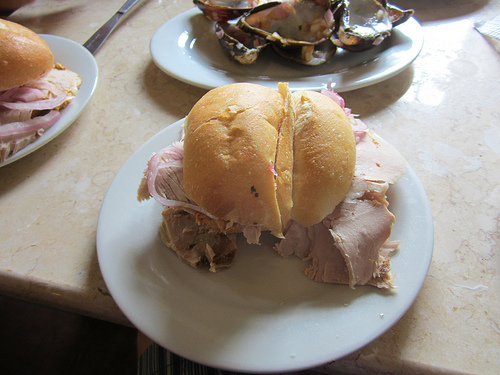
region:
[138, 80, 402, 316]
this is a sandwich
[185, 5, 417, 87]
this is a plate of food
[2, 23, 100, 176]
this is a plate of food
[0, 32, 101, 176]
this is a plate of food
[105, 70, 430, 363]
this is a plate of food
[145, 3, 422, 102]
this is a plate of food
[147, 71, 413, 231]
sandwich on the plate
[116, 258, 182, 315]
shadow on the plate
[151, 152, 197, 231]
meat in the sandwich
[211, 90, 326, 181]
brown bread on plate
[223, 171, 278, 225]
dark spot on bread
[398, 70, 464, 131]
light hitting the table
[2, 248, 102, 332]
edge of the table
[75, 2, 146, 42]
utensil next to the plate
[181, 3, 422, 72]
food on the plate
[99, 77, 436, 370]
this is a plate of food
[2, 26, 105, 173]
this is a plate of food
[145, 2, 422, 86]
this is a plate of food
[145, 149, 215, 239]
this is a ring of onion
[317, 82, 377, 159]
this is a ring of onion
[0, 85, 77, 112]
this is a ring of onion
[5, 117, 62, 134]
this is a ring of onion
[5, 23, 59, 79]
this is a piece of bread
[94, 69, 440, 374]
meat sandwich on white plate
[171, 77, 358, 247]
tan sandwich roll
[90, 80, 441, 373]
round white plate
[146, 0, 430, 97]
empty oyster shells on plate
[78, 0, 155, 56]
silver butter knife on table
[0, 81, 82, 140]
sliced onions on sandwich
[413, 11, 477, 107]
light reflecting on table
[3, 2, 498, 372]
cream colored marble table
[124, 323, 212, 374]
silver legs of table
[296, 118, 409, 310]
tan colored sandwich meat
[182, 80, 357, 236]
the top section of the bun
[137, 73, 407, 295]
the filled sandwich that hasn't been eaten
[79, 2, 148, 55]
the silver butter knife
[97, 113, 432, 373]
the round white plate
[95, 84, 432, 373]
the food on the white plate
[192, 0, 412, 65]
the empty clam shells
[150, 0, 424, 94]
the clam shells on the white plate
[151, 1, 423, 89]
the white plate under the clam shells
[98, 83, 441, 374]
sandwich on a plate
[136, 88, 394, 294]
meat on a sandwich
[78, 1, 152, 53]
knife on the table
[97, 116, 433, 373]
plate is white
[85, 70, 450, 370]
A sandwich on the plate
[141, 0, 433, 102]
A round white plate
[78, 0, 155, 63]
A silver butter knife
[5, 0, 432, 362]
white plates on the table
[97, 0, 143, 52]
silver knife on the table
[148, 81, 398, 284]
sandwich with pink meat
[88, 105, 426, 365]
plate hanging off the table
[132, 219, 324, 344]
shadow on the white plate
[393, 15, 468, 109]
light reflection on the table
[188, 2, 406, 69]
brown shell life food on the plate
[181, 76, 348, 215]
top bun on the sandwich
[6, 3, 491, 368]
beige table the plates are on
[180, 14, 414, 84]
shadows on the middle plate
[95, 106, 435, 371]
white plate is round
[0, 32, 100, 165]
white plate is round